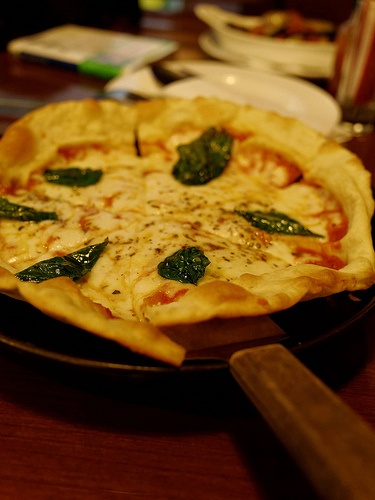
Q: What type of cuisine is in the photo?
A: Italian.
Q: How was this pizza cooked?
A: In the oven.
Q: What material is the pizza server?
A: Wood.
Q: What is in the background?
A: A table.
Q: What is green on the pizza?
A: Spinach.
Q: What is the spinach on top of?
A: Cheese.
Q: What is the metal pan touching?
A: Table top.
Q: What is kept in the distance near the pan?
A: White plate.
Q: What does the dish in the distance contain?
A: Food.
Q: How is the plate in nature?
A: Circular.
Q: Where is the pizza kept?
A: On the pan.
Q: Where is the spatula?
A: Under the pizza.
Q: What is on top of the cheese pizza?
A: Leaves.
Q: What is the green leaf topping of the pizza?
A: Basil.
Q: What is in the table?
A: Plate.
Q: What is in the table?
A: Food.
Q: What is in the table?
A: Pizz.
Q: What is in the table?
A: Fork.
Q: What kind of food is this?
A: Pizza.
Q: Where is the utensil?
A: Under the pizza.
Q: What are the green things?
A: Spinach.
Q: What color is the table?
A: Brown.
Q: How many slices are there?
A: Six.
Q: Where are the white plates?
A: Behind the pizza.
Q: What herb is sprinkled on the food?
A: Oregano.